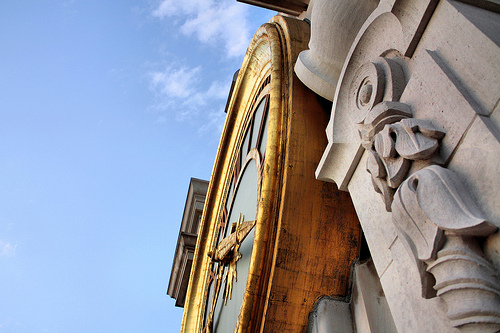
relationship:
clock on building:
[173, 16, 373, 326] [162, 3, 492, 331]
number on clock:
[248, 103, 270, 163] [173, 16, 373, 326]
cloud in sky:
[146, 60, 241, 133] [0, 1, 275, 331]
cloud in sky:
[154, 1, 251, 56] [0, 1, 275, 331]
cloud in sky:
[154, 1, 251, 56] [4, 2, 214, 169]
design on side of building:
[287, 1, 497, 331] [292, 0, 496, 330]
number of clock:
[225, 154, 243, 191] [156, 0, 303, 326]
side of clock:
[272, 173, 358, 302] [185, 16, 361, 333]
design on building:
[340, 60, 386, 127] [162, 3, 492, 331]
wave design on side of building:
[353, 117, 455, 204] [292, 0, 496, 330]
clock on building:
[185, 16, 361, 333] [162, 3, 492, 331]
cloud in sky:
[146, 60, 241, 133] [1, 5, 196, 325]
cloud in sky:
[146, 60, 227, 129] [0, 1, 275, 331]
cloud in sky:
[154, 1, 251, 56] [32, 61, 172, 233]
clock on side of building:
[173, 16, 373, 326] [127, 4, 494, 327]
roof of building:
[159, 171, 214, 306] [162, 3, 492, 331]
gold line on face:
[242, 111, 257, 149] [180, 27, 271, 330]